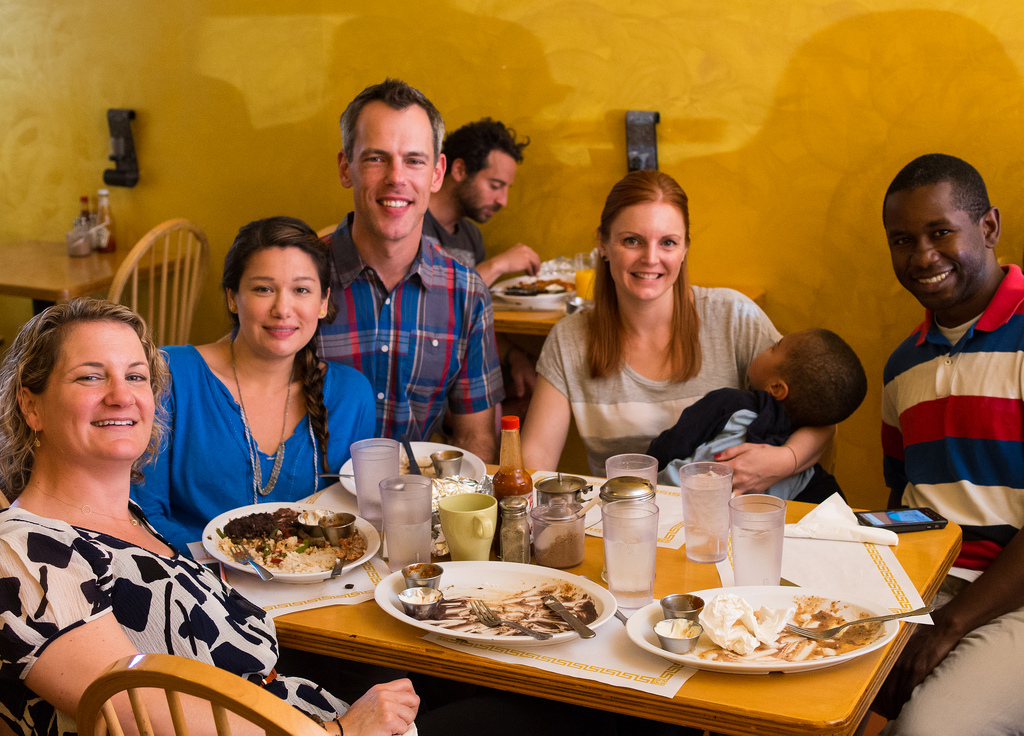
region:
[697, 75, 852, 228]
the wall is yellow in color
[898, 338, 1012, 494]
the shirt is blue,red and white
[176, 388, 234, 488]
the shirt is blue in color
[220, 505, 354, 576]
the plate has food on it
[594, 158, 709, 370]
the woman is white in color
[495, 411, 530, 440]
the lid is red in color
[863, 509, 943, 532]
the phone is on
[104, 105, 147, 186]
accessory attached to wall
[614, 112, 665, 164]
accessory attached to wall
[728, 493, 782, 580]
glass on top of table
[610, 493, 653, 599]
glass on top of table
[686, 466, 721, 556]
glass on top of table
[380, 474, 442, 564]
glass on top of table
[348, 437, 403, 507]
glass on top of table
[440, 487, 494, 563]
cup on top of table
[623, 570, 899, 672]
plate on top of table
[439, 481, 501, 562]
Yellow mug on top of the table.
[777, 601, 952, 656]
Silver fork on the side of the plate.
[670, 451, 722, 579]
Clear glass of water on top of the table.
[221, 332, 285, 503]
Silver necklace around the girl's neck.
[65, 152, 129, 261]
Bunch of condiments on top of the table.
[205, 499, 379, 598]
Plate of rice and food with utensils.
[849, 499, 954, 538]
Black cell phone sitting on top of the table.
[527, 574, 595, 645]
Dirty knife on the side of the plate.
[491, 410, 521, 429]
Red cap on top of the hot sauce.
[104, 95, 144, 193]
Candle holder on the side of the wall.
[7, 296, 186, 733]
Woman smiling in a black and white shirt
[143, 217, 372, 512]
A young woman sitting at a dinner table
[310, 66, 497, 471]
Man in a plaid shirt sitting at a dinner table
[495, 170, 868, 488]
A woman holding a sleeping child at a dinner table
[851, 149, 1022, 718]
Man in a red white and blue shirt sitting at dinner table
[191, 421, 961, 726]
Dinner table covered in dirty dishes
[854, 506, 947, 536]
Black smartphone on the table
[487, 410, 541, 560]
Bottle of tabasco sauce on the table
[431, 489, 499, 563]
White coffee mug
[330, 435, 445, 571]
Empty drinking glasses